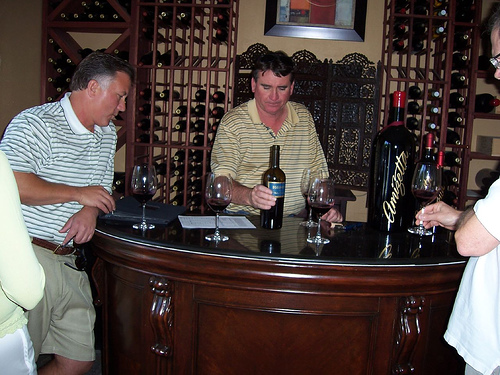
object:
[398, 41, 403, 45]
roses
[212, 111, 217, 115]
roses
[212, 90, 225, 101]
wine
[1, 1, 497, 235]
wall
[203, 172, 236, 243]
glass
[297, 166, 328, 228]
glass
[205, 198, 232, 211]
wine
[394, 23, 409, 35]
bottle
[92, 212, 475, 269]
bar top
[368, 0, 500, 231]
rack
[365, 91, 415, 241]
bottle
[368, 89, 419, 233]
bottle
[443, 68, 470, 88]
bottle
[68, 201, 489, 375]
counter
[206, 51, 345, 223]
man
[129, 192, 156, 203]
wine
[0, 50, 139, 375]
man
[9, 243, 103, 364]
khaki shorts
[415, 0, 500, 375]
man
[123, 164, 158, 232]
glass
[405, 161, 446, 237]
glasses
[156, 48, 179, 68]
bottle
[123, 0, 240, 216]
rack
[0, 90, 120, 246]
shirt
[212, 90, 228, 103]
wine bottle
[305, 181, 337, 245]
glass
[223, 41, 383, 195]
back sentence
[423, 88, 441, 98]
bottle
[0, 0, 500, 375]
bar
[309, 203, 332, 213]
wine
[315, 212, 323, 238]
stem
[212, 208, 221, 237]
stem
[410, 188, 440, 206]
wine